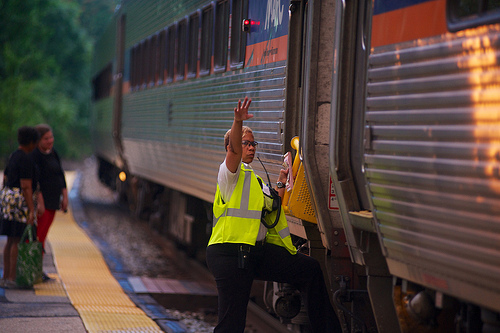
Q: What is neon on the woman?
A: Vest.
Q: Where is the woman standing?
A: Near train.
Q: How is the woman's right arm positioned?
A: Up.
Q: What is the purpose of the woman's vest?
A: Reflection.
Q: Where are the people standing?
A: Train platform.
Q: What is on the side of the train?
A: Windows.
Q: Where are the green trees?
A: Behind platform.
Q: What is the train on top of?
A: Tracks.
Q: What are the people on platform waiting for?
A: Train.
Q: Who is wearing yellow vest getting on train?
A: The woman.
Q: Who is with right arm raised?
A: The woman.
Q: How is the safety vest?
A: Neon yellow.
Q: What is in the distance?
A: Green trees.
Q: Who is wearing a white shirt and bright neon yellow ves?
A: A woman.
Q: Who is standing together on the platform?
A: Two women.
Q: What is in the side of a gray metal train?
A: Row of black window.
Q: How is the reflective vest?
A: Yellow and silver.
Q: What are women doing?
A: Waiting for train.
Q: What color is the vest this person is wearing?
A: Yellow.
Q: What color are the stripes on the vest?
A: Silver.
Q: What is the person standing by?
A: A train.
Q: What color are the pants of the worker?
A: Black.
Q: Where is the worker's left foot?
A: On the train steps.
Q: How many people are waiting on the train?
A: Two.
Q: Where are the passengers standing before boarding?
A: Behind yellow line.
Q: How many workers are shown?
A: One.